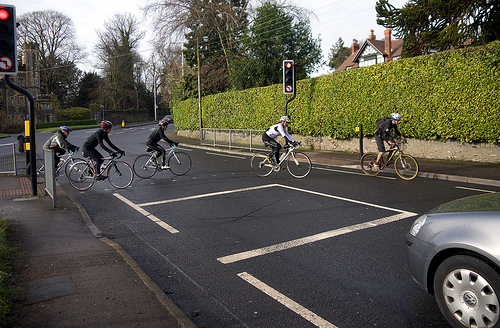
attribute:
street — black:
[10, 124, 406, 253]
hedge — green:
[173, 40, 498, 137]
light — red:
[1, 9, 9, 20]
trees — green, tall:
[185, 1, 313, 97]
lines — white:
[114, 192, 183, 237]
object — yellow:
[24, 121, 31, 142]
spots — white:
[148, 173, 221, 185]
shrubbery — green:
[323, 71, 495, 134]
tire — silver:
[442, 267, 498, 327]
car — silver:
[405, 188, 499, 309]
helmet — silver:
[281, 116, 293, 124]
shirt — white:
[265, 124, 293, 143]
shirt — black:
[86, 128, 123, 151]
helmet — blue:
[61, 125, 72, 133]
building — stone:
[347, 38, 411, 59]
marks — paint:
[276, 185, 429, 220]